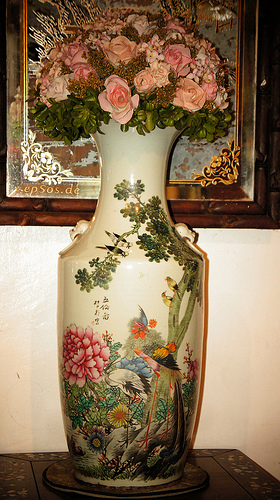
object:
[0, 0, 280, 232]
frame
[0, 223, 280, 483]
wall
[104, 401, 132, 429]
flower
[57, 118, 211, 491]
vase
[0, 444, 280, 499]
table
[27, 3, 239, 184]
framed picture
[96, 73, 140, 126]
flower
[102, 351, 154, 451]
bird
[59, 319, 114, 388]
flower